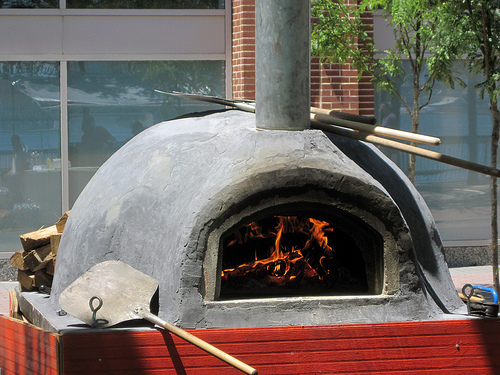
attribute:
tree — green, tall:
[320, 7, 474, 218]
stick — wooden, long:
[191, 88, 447, 146]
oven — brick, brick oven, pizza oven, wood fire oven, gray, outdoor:
[46, 2, 473, 321]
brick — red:
[333, 75, 349, 83]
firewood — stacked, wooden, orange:
[12, 210, 70, 298]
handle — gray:
[82, 290, 108, 333]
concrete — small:
[443, 249, 497, 296]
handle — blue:
[469, 284, 497, 305]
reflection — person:
[71, 108, 117, 166]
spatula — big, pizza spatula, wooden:
[52, 253, 255, 373]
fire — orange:
[244, 220, 357, 289]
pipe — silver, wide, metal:
[256, 0, 313, 130]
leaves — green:
[314, 3, 405, 79]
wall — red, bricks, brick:
[230, 3, 373, 115]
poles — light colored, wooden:
[162, 76, 497, 178]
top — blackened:
[172, 103, 395, 185]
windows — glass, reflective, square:
[4, 59, 231, 251]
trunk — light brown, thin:
[405, 26, 425, 196]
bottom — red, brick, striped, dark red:
[3, 315, 499, 373]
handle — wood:
[137, 309, 264, 374]